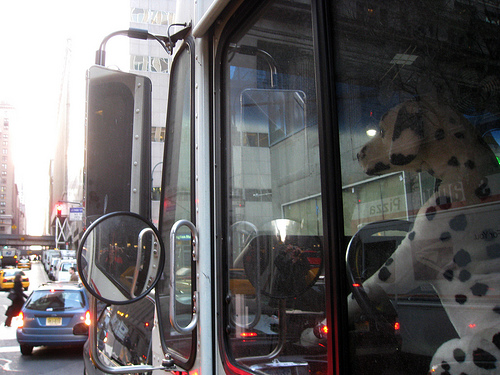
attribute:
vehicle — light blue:
[21, 277, 93, 354]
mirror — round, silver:
[32, 207, 204, 307]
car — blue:
[8, 273, 111, 368]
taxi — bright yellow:
[1, 266, 29, 291]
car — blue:
[13, 283, 95, 356]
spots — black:
[440, 250, 488, 304]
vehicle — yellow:
[3, 271, 31, 290]